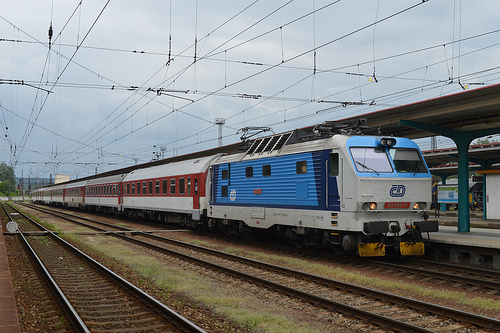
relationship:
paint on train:
[210, 164, 337, 210] [16, 110, 448, 282]